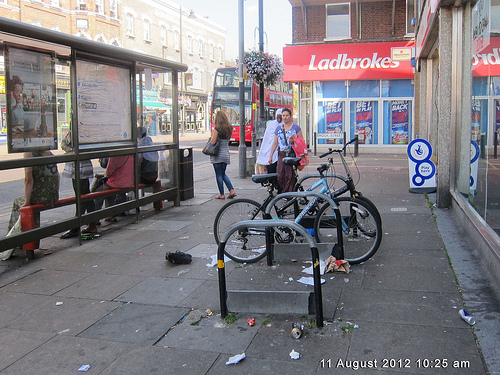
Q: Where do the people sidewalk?
A: Walking.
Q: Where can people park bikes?
A: The bike rack.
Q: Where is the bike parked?
A: At the bike rack.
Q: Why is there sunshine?
A: Because it's day time.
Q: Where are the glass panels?
A: On the bus stop.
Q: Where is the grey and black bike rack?
A: On the sidewalk.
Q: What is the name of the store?
A: Ladbrokes.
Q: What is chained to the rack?
A: Bicycles.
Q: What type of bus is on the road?
A: A double decker bus.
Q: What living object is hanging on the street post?
A: Flowers.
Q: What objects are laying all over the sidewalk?
A: Trash.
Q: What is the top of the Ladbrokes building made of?
A: Brick.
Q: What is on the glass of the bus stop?
A: Advertisements.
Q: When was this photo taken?
A: Daytime.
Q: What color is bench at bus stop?
A: Red.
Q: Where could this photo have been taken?
A: Down town.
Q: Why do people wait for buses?
A: For transportation.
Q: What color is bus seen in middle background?
A: Red.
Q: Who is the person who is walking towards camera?
A: Woman.